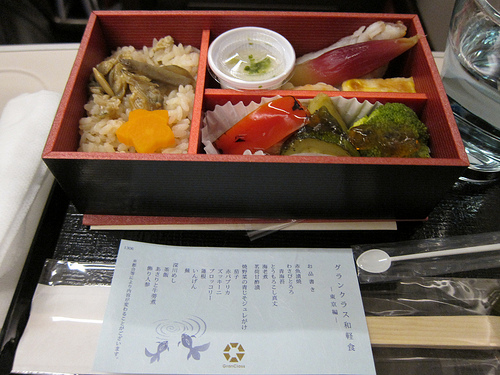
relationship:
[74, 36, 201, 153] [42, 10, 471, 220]
rice in box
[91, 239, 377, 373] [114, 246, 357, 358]
paper has writing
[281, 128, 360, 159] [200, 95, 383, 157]
zucchini on paper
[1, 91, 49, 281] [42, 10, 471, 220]
napkin next to box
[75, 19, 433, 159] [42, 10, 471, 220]
food in box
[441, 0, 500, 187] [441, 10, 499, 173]
glass has water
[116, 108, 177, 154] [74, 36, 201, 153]
star on rice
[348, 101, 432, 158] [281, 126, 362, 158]
broccoli next to zucchini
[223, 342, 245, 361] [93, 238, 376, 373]
logo on receipt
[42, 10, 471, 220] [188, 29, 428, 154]
box has dividers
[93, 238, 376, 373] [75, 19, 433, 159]
receipt for food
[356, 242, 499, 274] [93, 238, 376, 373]
utensil next to receipt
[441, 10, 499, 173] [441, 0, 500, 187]
water in glass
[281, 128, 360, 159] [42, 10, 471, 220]
zucchini in box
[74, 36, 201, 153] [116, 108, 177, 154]
rice under star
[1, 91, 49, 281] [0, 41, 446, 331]
napkin on table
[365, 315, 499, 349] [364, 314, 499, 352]
utensil made of wood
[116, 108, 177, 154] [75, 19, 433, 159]
star in food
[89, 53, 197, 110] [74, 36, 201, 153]
meat on rice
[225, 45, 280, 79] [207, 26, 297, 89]
sauce in container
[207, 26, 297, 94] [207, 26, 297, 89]
lid for container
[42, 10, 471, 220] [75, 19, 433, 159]
box full of food